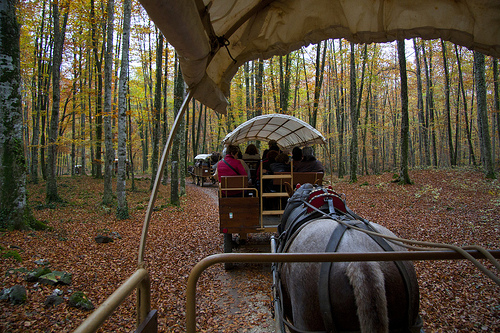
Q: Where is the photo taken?
A: In the woods.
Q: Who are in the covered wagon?
A: People.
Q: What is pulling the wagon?
A: A horse.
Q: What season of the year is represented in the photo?
A: Fall.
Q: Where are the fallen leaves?
A: On the ground.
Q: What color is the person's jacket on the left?
A: Red.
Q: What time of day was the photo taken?
A: Daytime.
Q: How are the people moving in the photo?
A: Riding in the wagons.